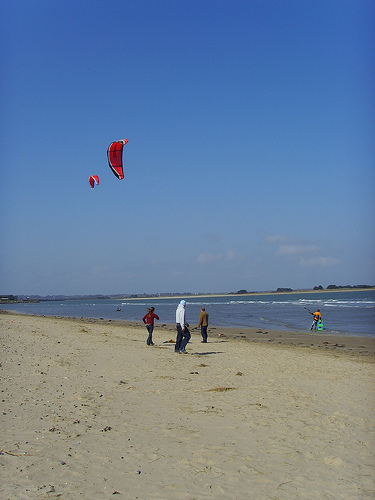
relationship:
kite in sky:
[58, 96, 166, 208] [8, 13, 372, 428]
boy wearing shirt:
[139, 304, 162, 347] [140, 312, 161, 324]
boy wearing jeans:
[140, 305, 159, 344] [145, 323, 154, 344]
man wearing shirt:
[172, 297, 191, 354] [172, 305, 186, 329]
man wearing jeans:
[197, 307, 209, 343] [198, 326, 210, 341]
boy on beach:
[141, 302, 159, 346] [215, 379, 283, 452]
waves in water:
[165, 281, 353, 330] [31, 269, 372, 386]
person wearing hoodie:
[160, 299, 222, 372] [169, 297, 218, 335]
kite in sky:
[105, 136, 129, 179] [0, 0, 373, 296]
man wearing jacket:
[194, 308, 213, 344] [195, 310, 211, 327]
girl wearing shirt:
[141, 306, 160, 346] [141, 311, 159, 323]